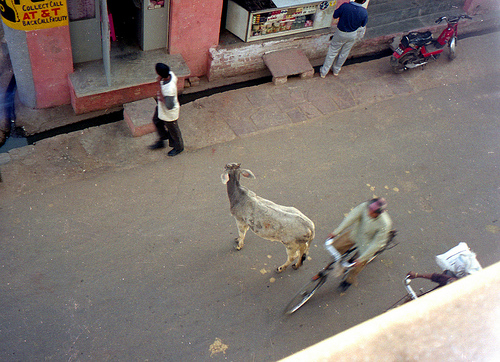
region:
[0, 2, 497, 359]
view of street from above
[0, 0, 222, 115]
storefront with open doorway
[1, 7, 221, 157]
walking man looking into doorway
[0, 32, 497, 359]
white and gray goat standing on steet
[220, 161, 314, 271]
top of goat with gray neck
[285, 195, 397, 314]
man with long sleeves riding bike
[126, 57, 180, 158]
a man standing by a step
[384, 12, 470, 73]
a parked scooter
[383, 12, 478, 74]
a red parked scooter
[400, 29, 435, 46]
a black seat on a scooter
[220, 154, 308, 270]
a goat standing on a street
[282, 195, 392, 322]
a man riding a bike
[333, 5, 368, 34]
a person wearing a blue shirt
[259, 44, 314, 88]
a wood step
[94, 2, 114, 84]
a grey metal pole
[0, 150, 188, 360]
a paved street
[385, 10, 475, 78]
a motorcycle on the side of the road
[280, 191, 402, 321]
a person riding the bicycle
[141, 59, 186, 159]
a person walking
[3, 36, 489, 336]
a road with people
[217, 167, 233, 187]
an ear of the animal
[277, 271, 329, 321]
wheel of the bicycle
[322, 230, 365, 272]
driving wheel of the bicycle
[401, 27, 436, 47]
a seat of the motorcycle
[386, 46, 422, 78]
a rear motorcycle wheel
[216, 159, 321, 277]
a grey and white goat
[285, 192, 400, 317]
man in light green sweater riding a bike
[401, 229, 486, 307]
bike rider carrying newspapers over his head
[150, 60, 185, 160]
person on the rural road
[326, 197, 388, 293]
person on the rural road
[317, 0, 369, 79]
person on the rural road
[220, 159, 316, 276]
cow on the rural road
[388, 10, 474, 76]
scooter on the rural road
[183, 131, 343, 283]
animal on the street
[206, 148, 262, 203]
head of the animal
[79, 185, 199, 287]
street next to animal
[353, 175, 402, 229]
head of a man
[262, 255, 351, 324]
front tire of the bike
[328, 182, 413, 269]
person wearing a shirt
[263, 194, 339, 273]
back of the animal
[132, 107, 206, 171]
legs of the person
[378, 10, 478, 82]
bike on the street